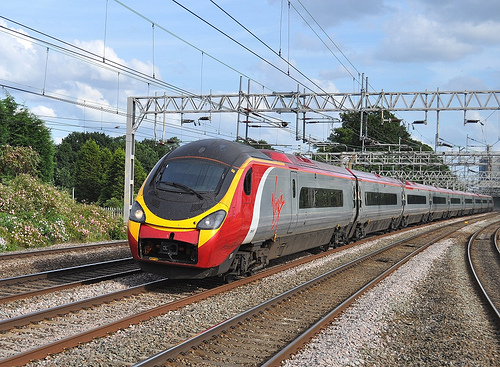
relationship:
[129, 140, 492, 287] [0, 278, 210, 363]
train on tracks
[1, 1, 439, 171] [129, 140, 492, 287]
wires above train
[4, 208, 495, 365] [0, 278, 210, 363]
gravel near tracks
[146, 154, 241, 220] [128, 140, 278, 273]
windshield in front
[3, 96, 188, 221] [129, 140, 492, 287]
trees near train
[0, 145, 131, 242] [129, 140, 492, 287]
flowers near train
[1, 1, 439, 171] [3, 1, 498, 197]
lines in sky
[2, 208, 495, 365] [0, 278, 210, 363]
set of tracks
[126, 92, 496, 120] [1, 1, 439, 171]
grids holding lines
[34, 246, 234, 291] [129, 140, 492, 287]
shadow of train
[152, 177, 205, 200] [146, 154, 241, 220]
wiper on windshield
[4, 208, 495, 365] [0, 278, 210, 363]
gravel between tracks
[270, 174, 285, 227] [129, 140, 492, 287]
writing on train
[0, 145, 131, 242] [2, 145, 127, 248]
flowers in bushes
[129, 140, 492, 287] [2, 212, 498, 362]
train on rails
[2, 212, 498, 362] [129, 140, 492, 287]
rails under train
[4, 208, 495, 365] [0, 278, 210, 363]
rocks on tracks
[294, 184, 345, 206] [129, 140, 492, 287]
window on train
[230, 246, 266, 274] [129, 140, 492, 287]
wheels on train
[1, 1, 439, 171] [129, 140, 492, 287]
lines above train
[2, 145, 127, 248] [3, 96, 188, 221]
bushes below trees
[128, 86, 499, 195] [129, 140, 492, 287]
metal over train